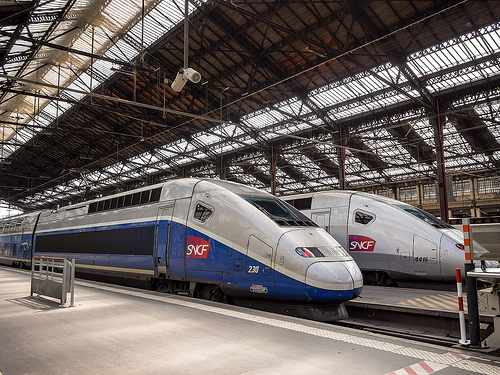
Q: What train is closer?
A: Blue.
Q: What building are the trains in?
A: Train station.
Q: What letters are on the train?
A: Sncf.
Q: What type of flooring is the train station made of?
A: Concrete.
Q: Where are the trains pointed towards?
A: Right.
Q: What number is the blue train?
A: 238.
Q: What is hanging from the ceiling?
A: Speakers.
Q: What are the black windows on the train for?
A: Viewing.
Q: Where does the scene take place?
A: At a train station.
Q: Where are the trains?
A: On train tracks.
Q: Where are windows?
A: On the trains.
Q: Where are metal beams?
A: On the ceiling.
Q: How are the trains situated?
A: Side by side.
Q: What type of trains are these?
A: Passenger.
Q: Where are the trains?
A: Train Station.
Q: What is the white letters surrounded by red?
A: SNCF.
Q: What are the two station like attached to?
A: Ceiling.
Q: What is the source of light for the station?
A: Windows.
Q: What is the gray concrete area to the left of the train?
A: Loading platform.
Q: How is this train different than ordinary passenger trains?
A: High Speed.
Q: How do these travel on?
A: Rail.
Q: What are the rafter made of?
A: Steel.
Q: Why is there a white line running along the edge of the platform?
A: Safety.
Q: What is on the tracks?
A: A train.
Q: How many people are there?
A: None.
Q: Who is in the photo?
A: No one.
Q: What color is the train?
A: Blue and silver.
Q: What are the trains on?
A: Tracks.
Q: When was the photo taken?
A: Daytime.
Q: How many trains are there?
A: Two.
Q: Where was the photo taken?
A: At a train station.